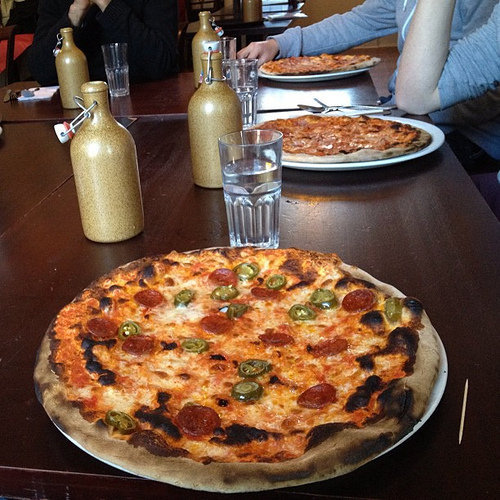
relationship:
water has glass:
[224, 159, 293, 249] [212, 121, 287, 251]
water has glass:
[235, 88, 259, 128] [228, 59, 257, 129]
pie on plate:
[35, 245, 441, 491] [25, 238, 461, 498]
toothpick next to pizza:
[456, 374, 470, 445] [35, 246, 439, 491]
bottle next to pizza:
[186, 47, 244, 190] [303, 124, 370, 161]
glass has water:
[214, 126, 291, 250] [230, 161, 270, 231]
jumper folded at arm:
[264, 0, 499, 164] [391, 0, 498, 117]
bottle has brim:
[184, 39, 234, 193] [60, 28, 74, 36]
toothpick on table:
[456, 378, 470, 444] [1, 57, 498, 497]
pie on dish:
[35, 245, 441, 491] [30, 243, 449, 495]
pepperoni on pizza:
[297, 378, 338, 410] [206, 72, 470, 186]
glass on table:
[217, 126, 284, 250] [1, 57, 498, 497]